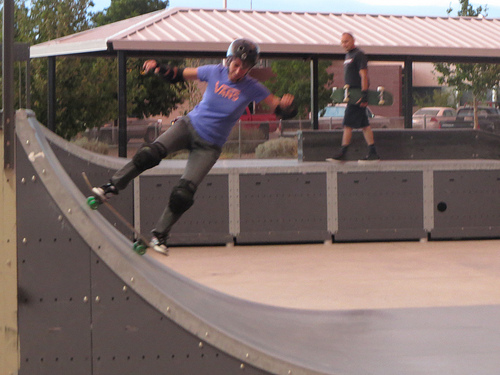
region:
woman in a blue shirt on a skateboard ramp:
[76, 10, 276, 286]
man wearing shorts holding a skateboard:
[317, 20, 395, 163]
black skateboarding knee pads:
[125, 133, 202, 217]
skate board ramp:
[41, 209, 486, 374]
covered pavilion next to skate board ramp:
[21, 11, 498, 151]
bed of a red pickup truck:
[233, 104, 279, 143]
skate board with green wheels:
[73, 165, 165, 267]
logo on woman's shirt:
[205, 71, 242, 118]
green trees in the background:
[7, 6, 150, 156]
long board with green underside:
[321, 77, 398, 114]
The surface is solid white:
[260, 248, 493, 300]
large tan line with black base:
[225, 168, 248, 257]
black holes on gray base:
[33, 231, 90, 331]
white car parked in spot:
[410, 104, 457, 133]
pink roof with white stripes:
[108, 9, 325, 48]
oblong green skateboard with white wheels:
[330, 81, 412, 118]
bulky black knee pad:
[125, 137, 175, 173]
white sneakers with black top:
[93, 177, 140, 203]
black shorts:
[335, 99, 373, 129]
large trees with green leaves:
[5, 4, 32, 111]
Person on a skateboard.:
[77, 35, 302, 256]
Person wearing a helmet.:
[60, 31, 300, 256]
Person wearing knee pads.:
[75, 35, 300, 260]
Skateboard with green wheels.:
[76, 166, 171, 261]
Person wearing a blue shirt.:
[77, 35, 297, 255]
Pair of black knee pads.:
[126, 140, 196, 215]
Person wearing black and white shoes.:
[80, 35, 302, 258]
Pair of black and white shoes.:
[90, 178, 170, 254]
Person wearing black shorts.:
[322, 30, 392, 161]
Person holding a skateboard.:
[325, 32, 395, 162]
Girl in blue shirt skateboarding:
[72, 18, 302, 273]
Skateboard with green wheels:
[68, 171, 183, 273]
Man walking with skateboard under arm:
[311, 25, 406, 162]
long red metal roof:
[11, 3, 498, 75]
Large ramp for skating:
[8, 107, 225, 374]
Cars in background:
[408, 98, 495, 136]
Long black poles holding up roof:
[104, 51, 147, 169]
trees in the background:
[12, 3, 148, 137]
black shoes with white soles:
[324, 144, 388, 171]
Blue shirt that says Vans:
[192, 64, 259, 149]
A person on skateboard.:
[80, 35, 298, 257]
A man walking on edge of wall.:
[325, 30, 395, 165]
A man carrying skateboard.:
[321, 30, 392, 165]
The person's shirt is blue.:
[182, 62, 270, 154]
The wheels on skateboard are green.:
[79, 186, 156, 256]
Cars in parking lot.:
[411, 101, 494, 133]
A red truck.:
[233, 106, 287, 136]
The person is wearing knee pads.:
[125, 141, 207, 217]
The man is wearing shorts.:
[337, 96, 375, 134]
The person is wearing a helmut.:
[216, 35, 261, 81]